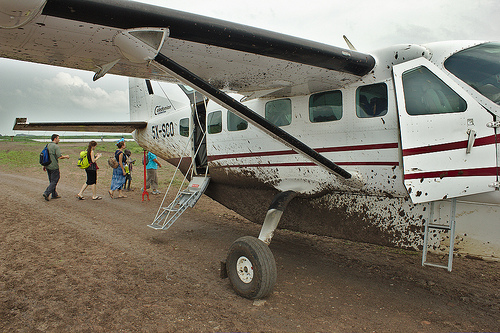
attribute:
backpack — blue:
[37, 145, 55, 175]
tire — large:
[204, 214, 295, 319]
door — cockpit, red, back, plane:
[374, 41, 486, 227]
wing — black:
[31, 19, 353, 110]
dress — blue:
[100, 157, 137, 201]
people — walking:
[12, 126, 186, 219]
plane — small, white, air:
[213, 83, 441, 226]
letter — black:
[143, 112, 178, 141]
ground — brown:
[76, 230, 117, 280]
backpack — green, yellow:
[73, 145, 101, 181]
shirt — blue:
[30, 143, 85, 167]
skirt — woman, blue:
[99, 168, 132, 195]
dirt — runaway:
[65, 227, 115, 269]